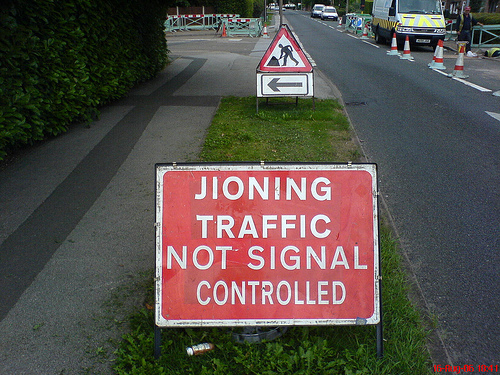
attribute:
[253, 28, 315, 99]
sign —  men working,  red, black and white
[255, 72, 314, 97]
sign —  black and white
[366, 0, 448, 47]
truck —  yellow and white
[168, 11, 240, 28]
fence —  in distance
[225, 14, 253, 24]
stripes —  red and white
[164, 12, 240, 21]
stripes —  red and white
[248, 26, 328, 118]
sign — construction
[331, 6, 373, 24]
person —  walking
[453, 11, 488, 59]
worker — construction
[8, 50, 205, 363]
sidewalk — grey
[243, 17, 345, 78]
corner — street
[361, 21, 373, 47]
cone —  white and orange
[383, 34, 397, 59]
cone —  white and orange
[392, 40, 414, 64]
cone —  white and orange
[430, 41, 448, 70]
cone —  white and orange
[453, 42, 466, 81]
cone —  white and orange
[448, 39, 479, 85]
cone street — safety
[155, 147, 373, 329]
sign —  red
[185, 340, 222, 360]
bottle —  small 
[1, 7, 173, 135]
bushes — manicured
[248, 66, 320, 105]
arrow —  pointing left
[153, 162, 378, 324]
sign — jioning traffic not signal controlled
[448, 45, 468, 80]
traffic cone — orange, white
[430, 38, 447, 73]
traffic cone — orange, white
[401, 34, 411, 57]
traffic cone — orange, white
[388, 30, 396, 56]
traffic cone — orange, white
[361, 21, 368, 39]
traffic cone — orange, white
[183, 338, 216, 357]
bottle — small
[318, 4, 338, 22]
car —  white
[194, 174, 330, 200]
word —  jioning 